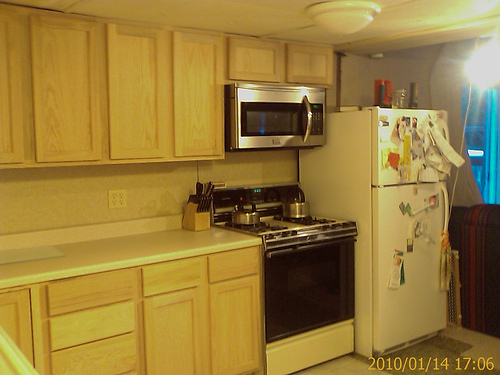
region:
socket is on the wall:
[105, 185, 127, 211]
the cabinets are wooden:
[17, 20, 206, 152]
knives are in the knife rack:
[196, 186, 214, 208]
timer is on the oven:
[248, 182, 281, 207]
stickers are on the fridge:
[396, 190, 441, 249]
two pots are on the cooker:
[232, 192, 315, 222]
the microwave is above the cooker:
[236, 90, 331, 149]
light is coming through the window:
[459, 56, 499, 94]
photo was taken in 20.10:
[356, 347, 497, 373]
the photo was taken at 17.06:
[449, 353, 499, 373]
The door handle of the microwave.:
[299, 93, 311, 142]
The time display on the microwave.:
[307, 101, 320, 108]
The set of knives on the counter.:
[184, 183, 215, 232]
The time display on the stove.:
[250, 188, 263, 191]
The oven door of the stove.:
[268, 228, 359, 333]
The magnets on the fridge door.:
[383, 113, 442, 291]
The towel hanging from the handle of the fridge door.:
[442, 242, 449, 304]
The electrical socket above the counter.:
[107, 188, 127, 211]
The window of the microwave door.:
[239, 103, 303, 136]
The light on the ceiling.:
[308, 0, 379, 36]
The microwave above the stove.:
[232, 83, 326, 148]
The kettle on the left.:
[232, 200, 259, 227]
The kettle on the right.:
[281, 186, 312, 216]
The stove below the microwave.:
[216, 177, 367, 371]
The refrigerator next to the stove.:
[315, 110, 450, 356]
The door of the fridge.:
[372, 180, 451, 342]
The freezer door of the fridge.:
[369, 109, 449, 179]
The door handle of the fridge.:
[439, 186, 451, 241]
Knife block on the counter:
[172, 177, 224, 238]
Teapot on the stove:
[222, 186, 269, 236]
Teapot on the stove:
[274, 183, 319, 226]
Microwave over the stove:
[223, 70, 341, 157]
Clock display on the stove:
[248, 180, 267, 199]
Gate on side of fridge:
[438, 241, 477, 340]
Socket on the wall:
[94, 182, 139, 217]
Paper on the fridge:
[381, 243, 415, 298]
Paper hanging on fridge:
[411, 110, 465, 189]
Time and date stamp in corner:
[357, 348, 498, 374]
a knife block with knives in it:
[178, 179, 221, 234]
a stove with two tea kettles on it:
[210, 181, 357, 243]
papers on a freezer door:
[377, 109, 459, 183]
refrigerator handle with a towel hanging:
[436, 181, 454, 298]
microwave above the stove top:
[218, 34, 358, 249]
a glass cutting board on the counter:
[3, 232, 73, 267]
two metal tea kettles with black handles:
[211, 173, 323, 230]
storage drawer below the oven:
[255, 315, 375, 365]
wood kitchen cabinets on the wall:
[20, 6, 238, 178]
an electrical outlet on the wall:
[89, 178, 179, 263]